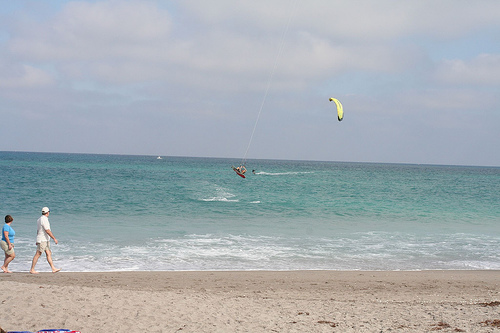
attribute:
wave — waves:
[189, 181, 261, 206]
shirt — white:
[32, 214, 56, 246]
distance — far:
[2, 5, 498, 259]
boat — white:
[155, 147, 170, 164]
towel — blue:
[3, 324, 73, 332]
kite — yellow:
[317, 85, 369, 131]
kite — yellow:
[319, 89, 352, 144]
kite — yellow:
[324, 93, 348, 124]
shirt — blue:
[3, 221, 15, 244]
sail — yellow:
[320, 92, 348, 129]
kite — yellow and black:
[304, 90, 347, 129]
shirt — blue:
[0, 228, 18, 242]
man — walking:
[21, 199, 62, 290]